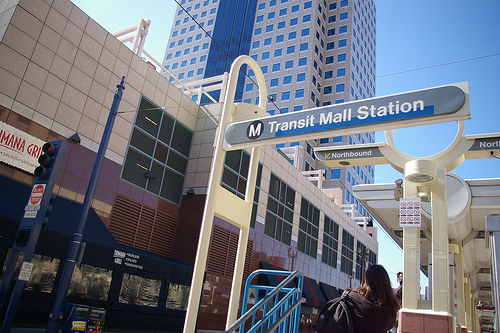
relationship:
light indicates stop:
[0, 140, 68, 331] [43, 142, 54, 156]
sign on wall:
[1, 118, 46, 177] [0, 111, 125, 217]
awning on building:
[3, 174, 208, 290] [1, 0, 381, 332]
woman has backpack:
[322, 263, 403, 332] [314, 288, 355, 332]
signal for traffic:
[0, 140, 68, 331] [3, 232, 402, 332]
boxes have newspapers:
[64, 299, 109, 332] [77, 309, 103, 322]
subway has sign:
[224, 62, 499, 332] [223, 79, 474, 150]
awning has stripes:
[262, 260, 362, 316] [303, 279, 322, 307]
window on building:
[116, 271, 166, 312] [1, 0, 381, 332]